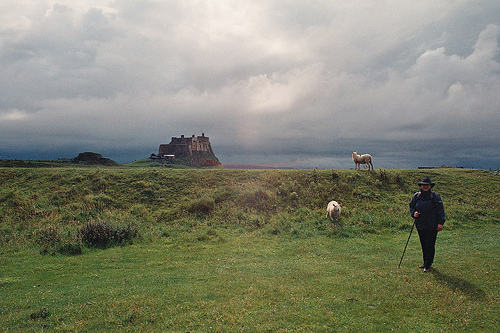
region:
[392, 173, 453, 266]
man walking on grass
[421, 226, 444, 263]
black pants of man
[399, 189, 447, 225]
black shirt of man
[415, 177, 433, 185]
black hat of man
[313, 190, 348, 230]
white sheep walking down embankment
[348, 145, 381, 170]
sheep standing on pathway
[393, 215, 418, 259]
walking stick of man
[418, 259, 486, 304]
man's shadow on the grass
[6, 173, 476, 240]
grass growing on embankment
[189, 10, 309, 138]
sun shining through clouds.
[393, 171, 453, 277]
a women in the grass field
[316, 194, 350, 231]
the lamb on the hillside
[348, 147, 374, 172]
the lamb on the top of the hill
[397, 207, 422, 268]
the cane in the womens hand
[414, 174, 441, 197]
the hat on the womens head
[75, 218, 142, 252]
the weeds on the bottom of the hill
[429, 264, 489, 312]
the shadow of the women in the grass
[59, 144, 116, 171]
A small hill in the middle of the field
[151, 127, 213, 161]
a building on the edge of the cliff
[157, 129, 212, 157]
the building on the hill top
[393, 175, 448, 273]
a woman standing in a field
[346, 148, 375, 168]
a sheep standing on top of a little hill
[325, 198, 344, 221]
another sheep walking towards the woman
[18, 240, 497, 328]
a whole lot of green grass on the ground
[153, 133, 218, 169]
a castle on top of a hill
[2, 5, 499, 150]
many large and mostly white clouds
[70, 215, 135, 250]
a little bush with a lot of green leaves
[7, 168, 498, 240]
a short little hill covered in grass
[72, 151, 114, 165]
another hill farther in the background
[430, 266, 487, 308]
the shadow of the woman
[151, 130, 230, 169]
A rustic castle in the background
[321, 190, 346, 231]
A sheep in the pasture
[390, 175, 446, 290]
A man with a cane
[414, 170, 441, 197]
A man wearing a hat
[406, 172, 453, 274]
A man standing on the grass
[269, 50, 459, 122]
Many clouds in the sky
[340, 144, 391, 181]
The side of a white sheep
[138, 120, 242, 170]
A castle on a mound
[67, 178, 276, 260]
Green lush grass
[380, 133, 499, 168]
Blue waters in the background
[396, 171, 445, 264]
person walking in field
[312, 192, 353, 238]
white sheep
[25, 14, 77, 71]
white clouds in blue sky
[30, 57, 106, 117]
white clouds in blue sky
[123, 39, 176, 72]
white clouds in blue sky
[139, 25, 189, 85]
white clouds in blue sky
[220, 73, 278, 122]
white clouds in blue sky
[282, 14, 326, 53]
white clouds in blue sky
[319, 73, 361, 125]
white clouds in blue sky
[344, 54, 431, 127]
white clouds in blue sky